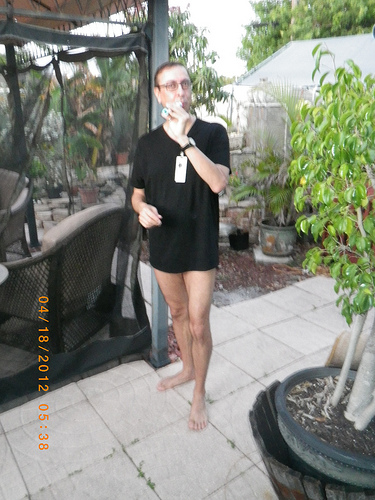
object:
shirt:
[130, 117, 232, 274]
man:
[129, 61, 231, 432]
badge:
[174, 151, 188, 184]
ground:
[341, 33, 374, 73]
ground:
[260, 96, 281, 121]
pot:
[228, 217, 297, 256]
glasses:
[155, 78, 192, 91]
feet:
[156, 366, 209, 431]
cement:
[0, 271, 375, 500]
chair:
[0, 203, 123, 361]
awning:
[0, 1, 150, 48]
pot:
[274, 366, 375, 490]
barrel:
[247, 378, 373, 499]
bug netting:
[0, 0, 152, 405]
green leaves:
[287, 42, 375, 329]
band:
[181, 143, 192, 151]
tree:
[286, 39, 375, 432]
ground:
[0, 189, 371, 498]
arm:
[179, 137, 230, 194]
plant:
[227, 74, 306, 226]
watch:
[181, 136, 196, 152]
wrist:
[177, 134, 195, 153]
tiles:
[0, 272, 367, 497]